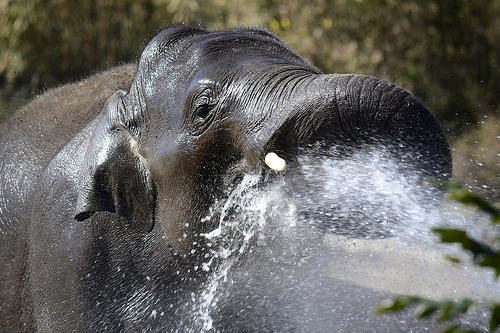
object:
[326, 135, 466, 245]
water droplets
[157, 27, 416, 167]
wrinkly skin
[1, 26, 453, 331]
animal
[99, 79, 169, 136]
skin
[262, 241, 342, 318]
droplets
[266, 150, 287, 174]
tusk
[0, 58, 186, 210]
back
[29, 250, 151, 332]
arm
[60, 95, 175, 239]
ear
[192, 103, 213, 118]
eye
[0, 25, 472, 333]
elephant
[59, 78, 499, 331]
water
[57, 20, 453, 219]
head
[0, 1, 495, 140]
trees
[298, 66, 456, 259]
trunk